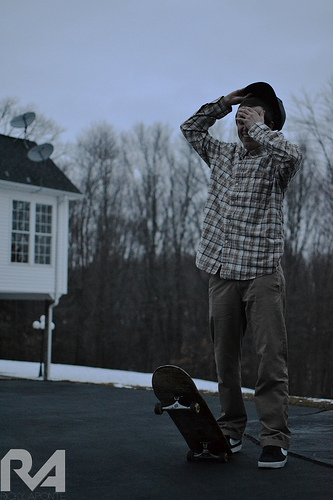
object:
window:
[11, 199, 53, 264]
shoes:
[224, 436, 243, 453]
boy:
[179, 81, 303, 469]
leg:
[208, 279, 249, 440]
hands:
[228, 89, 253, 105]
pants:
[208, 266, 292, 450]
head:
[235, 91, 275, 149]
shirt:
[178, 95, 302, 282]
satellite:
[27, 142, 54, 164]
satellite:
[10, 111, 35, 138]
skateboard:
[151, 363, 234, 464]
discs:
[27, 142, 54, 162]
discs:
[10, 111, 36, 127]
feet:
[258, 445, 288, 469]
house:
[0, 134, 83, 381]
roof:
[0, 133, 85, 201]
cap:
[239, 81, 287, 132]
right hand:
[235, 107, 262, 132]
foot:
[224, 436, 243, 453]